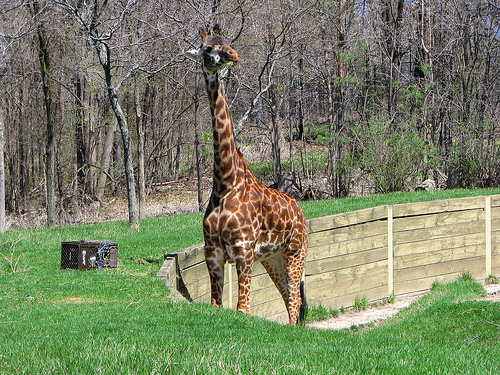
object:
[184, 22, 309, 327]
giraffe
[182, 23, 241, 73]
head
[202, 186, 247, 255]
chest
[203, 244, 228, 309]
leg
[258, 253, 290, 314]
leg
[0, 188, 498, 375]
grass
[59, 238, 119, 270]
crate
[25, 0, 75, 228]
many trees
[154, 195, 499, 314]
wall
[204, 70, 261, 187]
neck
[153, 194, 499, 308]
enclosure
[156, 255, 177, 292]
wooden boards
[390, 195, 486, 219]
board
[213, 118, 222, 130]
spot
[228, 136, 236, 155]
spot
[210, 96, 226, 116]
spot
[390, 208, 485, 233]
board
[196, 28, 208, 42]
horn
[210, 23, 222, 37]
horn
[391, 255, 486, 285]
board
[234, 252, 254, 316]
leg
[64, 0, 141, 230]
tree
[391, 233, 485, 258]
board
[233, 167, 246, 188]
spot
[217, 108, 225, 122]
spot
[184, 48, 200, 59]
ear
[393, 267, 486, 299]
board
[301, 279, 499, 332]
ground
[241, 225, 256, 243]
spot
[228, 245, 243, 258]
spot